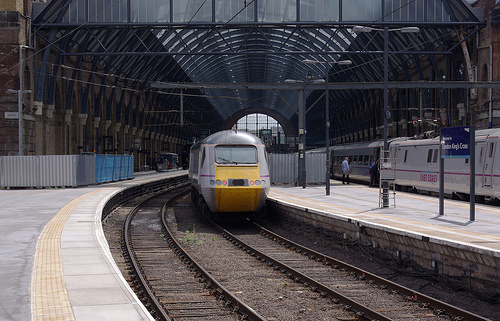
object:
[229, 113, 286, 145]
window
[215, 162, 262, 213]
front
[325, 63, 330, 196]
pole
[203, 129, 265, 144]
top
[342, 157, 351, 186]
man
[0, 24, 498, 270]
scene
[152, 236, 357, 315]
railwayline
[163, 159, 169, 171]
people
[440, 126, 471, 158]
sign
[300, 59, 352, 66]
lamp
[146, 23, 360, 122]
roof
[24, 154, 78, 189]
wall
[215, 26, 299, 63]
panes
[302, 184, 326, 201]
grass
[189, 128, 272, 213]
train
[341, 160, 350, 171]
shirt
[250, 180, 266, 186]
light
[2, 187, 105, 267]
area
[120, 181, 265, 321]
track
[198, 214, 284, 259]
railway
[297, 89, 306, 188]
post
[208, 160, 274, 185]
number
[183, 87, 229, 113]
cable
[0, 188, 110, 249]
platform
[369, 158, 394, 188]
bin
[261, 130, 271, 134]
mirror